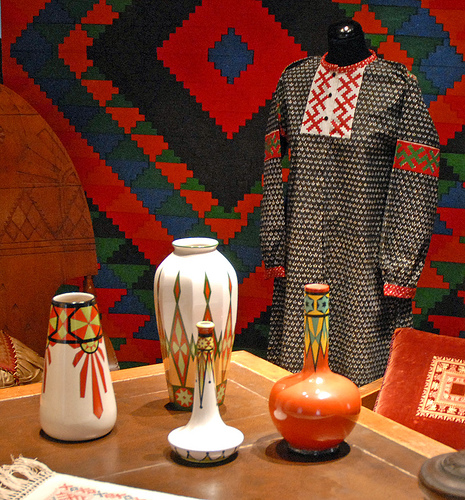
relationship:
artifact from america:
[168, 322, 245, 467] [443, 29, 459, 51]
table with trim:
[0, 345, 462, 498] [195, 114, 221, 128]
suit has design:
[260, 49, 439, 387] [300, 52, 376, 136]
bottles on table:
[34, 236, 362, 466] [0, 345, 462, 498]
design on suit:
[265, 130, 440, 178] [260, 49, 439, 387]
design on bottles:
[302, 290, 331, 369] [263, 281, 362, 458]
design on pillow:
[413, 354, 463, 420] [372, 325, 463, 447]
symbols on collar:
[321, 49, 378, 72] [319, 47, 377, 75]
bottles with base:
[263, 281, 362, 458] [287, 438, 341, 454]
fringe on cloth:
[0, 449, 44, 499] [0, 456, 199, 499]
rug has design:
[0, 327, 49, 384] [0, 341, 7, 364]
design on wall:
[0, 0, 461, 362] [0, 0, 463, 406]